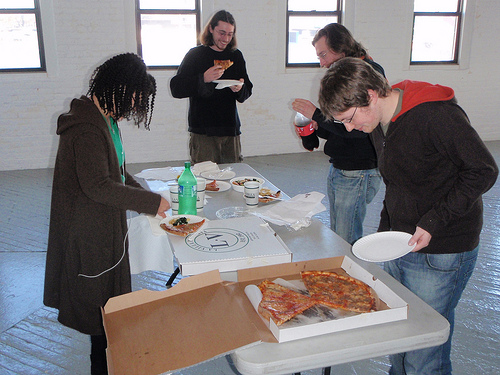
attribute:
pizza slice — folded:
[213, 59, 234, 71]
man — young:
[318, 56, 499, 374]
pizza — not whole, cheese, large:
[256, 270, 380, 326]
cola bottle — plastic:
[294, 111, 320, 151]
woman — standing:
[43, 52, 171, 374]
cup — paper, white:
[243, 180, 262, 208]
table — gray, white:
[140, 162, 450, 374]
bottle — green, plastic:
[177, 161, 198, 216]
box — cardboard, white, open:
[100, 254, 409, 374]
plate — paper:
[159, 214, 208, 237]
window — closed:
[1, 1, 47, 74]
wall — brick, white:
[0, 0, 499, 172]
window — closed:
[134, 0, 201, 70]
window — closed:
[285, 0, 342, 68]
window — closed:
[410, 0, 464, 65]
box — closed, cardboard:
[166, 215, 294, 277]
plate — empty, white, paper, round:
[351, 230, 417, 263]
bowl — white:
[230, 175, 266, 193]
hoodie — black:
[367, 79, 499, 255]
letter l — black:
[210, 240, 231, 249]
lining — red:
[390, 79, 455, 122]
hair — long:
[199, 10, 236, 50]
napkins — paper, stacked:
[249, 191, 326, 232]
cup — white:
[196, 177, 207, 211]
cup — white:
[167, 183, 179, 216]